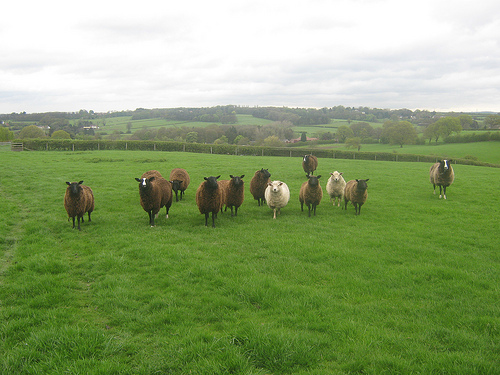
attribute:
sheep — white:
[262, 177, 290, 214]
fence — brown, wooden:
[11, 137, 492, 173]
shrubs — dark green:
[112, 114, 396, 191]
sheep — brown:
[131, 171, 177, 230]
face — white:
[139, 175, 148, 186]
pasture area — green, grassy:
[40, 242, 494, 364]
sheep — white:
[262, 176, 292, 220]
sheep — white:
[134, 174, 174, 229]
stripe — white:
[141, 177, 144, 186]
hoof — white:
[164, 214, 169, 220]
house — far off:
[26, 120, 103, 141]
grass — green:
[4, 152, 498, 371]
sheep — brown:
[256, 174, 300, 214]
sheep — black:
[244, 166, 276, 207]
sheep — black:
[62, 180, 96, 228]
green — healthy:
[368, 255, 464, 287]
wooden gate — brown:
[1, 137, 30, 154]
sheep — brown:
[58, 178, 98, 228]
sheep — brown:
[170, 164, 190, 200]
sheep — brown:
[195, 173, 225, 225]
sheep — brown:
[220, 173, 247, 216]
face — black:
[205, 174, 221, 194]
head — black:
[63, 176, 86, 197]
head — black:
[202, 173, 221, 195]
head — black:
[227, 172, 244, 190]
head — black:
[168, 177, 185, 191]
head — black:
[303, 172, 323, 190]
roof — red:
[79, 124, 100, 128]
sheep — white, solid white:
[322, 168, 348, 208]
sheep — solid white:
[261, 179, 291, 213]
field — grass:
[8, 129, 498, 369]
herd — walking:
[56, 167, 476, 216]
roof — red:
[291, 135, 319, 141]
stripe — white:
[445, 155, 450, 168]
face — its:
[436, 155, 455, 175]